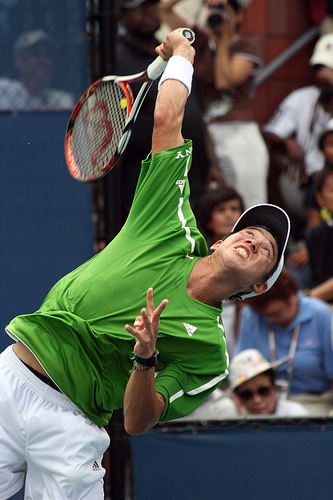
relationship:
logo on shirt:
[183, 320, 197, 337] [4, 139, 230, 430]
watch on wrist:
[131, 349, 163, 367] [130, 351, 159, 370]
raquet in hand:
[64, 28, 194, 183] [155, 30, 197, 61]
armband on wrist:
[157, 54, 193, 95] [171, 44, 195, 73]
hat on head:
[229, 199, 289, 302] [220, 222, 281, 284]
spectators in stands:
[4, 3, 333, 417] [0, 4, 332, 420]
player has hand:
[2, 26, 289, 499] [124, 286, 169, 354]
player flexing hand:
[2, 26, 289, 499] [124, 286, 169, 354]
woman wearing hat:
[206, 348, 307, 420] [213, 347, 292, 408]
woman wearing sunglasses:
[206, 348, 307, 420] [240, 384, 271, 402]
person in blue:
[234, 272, 332, 414] [233, 293, 332, 390]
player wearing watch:
[2, 26, 289, 499] [131, 349, 163, 367]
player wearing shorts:
[2, 26, 289, 499] [0, 345, 112, 500]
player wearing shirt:
[2, 26, 289, 499] [4, 139, 230, 430]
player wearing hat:
[2, 26, 289, 499] [229, 199, 289, 302]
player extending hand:
[2, 26, 289, 499] [155, 30, 197, 61]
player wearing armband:
[2, 26, 289, 499] [157, 54, 193, 95]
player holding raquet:
[2, 26, 289, 499] [64, 28, 194, 183]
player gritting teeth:
[2, 26, 289, 499] [235, 243, 250, 259]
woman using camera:
[192, 0, 270, 206] [203, 10, 226, 31]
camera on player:
[203, 10, 226, 31] [2, 26, 289, 499]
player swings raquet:
[2, 26, 289, 499] [64, 28, 194, 183]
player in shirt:
[2, 26, 289, 499] [4, 139, 230, 430]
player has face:
[2, 26, 289, 499] [218, 226, 278, 285]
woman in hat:
[206, 348, 307, 420] [213, 347, 292, 408]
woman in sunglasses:
[206, 348, 307, 420] [240, 384, 271, 402]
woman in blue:
[206, 348, 307, 420] [233, 293, 332, 390]